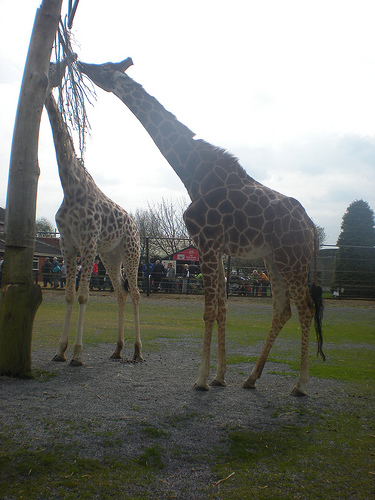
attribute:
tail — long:
[310, 222, 326, 365]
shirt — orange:
[260, 273, 268, 281]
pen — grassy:
[0, 290, 355, 498]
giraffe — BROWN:
[78, 59, 328, 389]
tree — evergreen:
[335, 199, 362, 303]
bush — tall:
[330, 199, 362, 282]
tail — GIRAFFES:
[310, 244, 326, 362]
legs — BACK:
[242, 254, 321, 397]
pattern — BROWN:
[86, 199, 106, 229]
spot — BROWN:
[200, 250, 217, 265]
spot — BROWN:
[204, 272, 210, 289]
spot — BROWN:
[207, 287, 217, 295]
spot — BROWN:
[271, 244, 290, 268]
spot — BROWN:
[292, 259, 303, 273]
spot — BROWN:
[230, 205, 249, 233]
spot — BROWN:
[201, 222, 226, 241]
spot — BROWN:
[185, 197, 208, 226]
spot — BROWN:
[304, 227, 316, 244]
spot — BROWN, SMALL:
[201, 221, 225, 242]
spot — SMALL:
[220, 213, 232, 230]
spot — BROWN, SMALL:
[231, 207, 246, 232]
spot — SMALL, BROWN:
[243, 224, 259, 241]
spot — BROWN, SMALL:
[247, 209, 265, 232]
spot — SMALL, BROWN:
[227, 188, 247, 209]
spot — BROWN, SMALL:
[272, 245, 289, 266]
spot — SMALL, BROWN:
[284, 267, 294, 279]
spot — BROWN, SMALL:
[295, 284, 305, 301]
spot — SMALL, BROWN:
[247, 192, 260, 204]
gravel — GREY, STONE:
[10, 351, 299, 452]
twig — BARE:
[210, 464, 237, 488]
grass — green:
[132, 416, 176, 442]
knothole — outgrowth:
[29, 279, 46, 316]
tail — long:
[309, 216, 330, 366]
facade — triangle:
[157, 243, 202, 265]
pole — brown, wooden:
[143, 234, 151, 297]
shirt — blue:
[49, 266, 61, 276]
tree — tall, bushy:
[337, 193, 363, 297]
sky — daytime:
[0, 2, 361, 239]